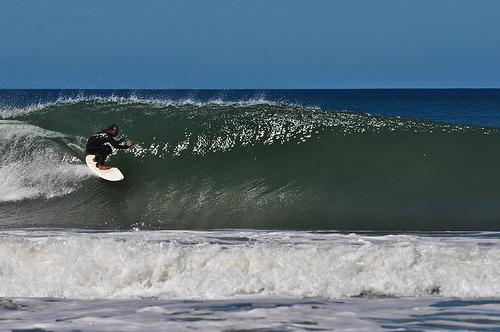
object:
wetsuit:
[86, 131, 129, 154]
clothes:
[86, 129, 128, 165]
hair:
[107, 124, 114, 130]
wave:
[0, 94, 500, 205]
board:
[85, 154, 124, 181]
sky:
[4, 8, 495, 88]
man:
[86, 124, 134, 170]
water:
[282, 185, 496, 234]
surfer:
[85, 123, 135, 169]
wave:
[0, 224, 500, 332]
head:
[102, 124, 119, 137]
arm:
[108, 136, 134, 149]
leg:
[88, 146, 111, 167]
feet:
[99, 164, 111, 170]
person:
[85, 124, 134, 170]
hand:
[120, 138, 126, 143]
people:
[85, 124, 135, 170]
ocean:
[0, 86, 499, 332]